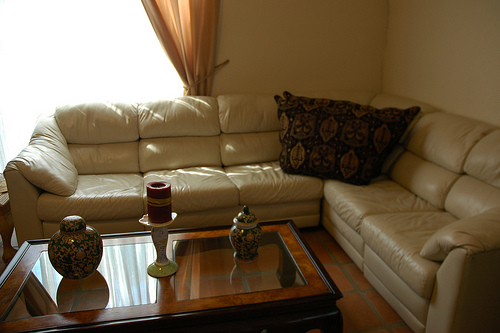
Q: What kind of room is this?
A: Living room.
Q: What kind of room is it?
A: A living room.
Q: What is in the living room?
A: A couch.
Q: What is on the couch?
A: A pillow.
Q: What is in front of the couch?
A: A table.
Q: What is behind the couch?
A: A wall.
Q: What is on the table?
A: Glass.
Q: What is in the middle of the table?
A: A skinny vase.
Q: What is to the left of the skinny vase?
A: A round vase.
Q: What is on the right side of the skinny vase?
A: A small vase.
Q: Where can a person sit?
A: Couch.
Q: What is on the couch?
A: Pillow.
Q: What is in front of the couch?
A: Coffee table.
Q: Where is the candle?
A: Middle of the coffee table.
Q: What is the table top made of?
A: Glass.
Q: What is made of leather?
A: The couch.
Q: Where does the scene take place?
A: In a living room.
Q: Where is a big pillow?
A: On the couch.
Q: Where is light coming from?
A: Windows.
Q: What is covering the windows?
A: Curtains.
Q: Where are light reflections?
A: On coffee table.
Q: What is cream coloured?
A: Couch.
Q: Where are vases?
A: On coffee table.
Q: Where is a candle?
A: On candle holder.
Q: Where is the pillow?
A: On the couch.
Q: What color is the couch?
A: Tan.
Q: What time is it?
A: Day time.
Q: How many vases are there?
A: Two.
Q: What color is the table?
A: Brown.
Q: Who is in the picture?
A: No one.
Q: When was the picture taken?
A: Daytime.